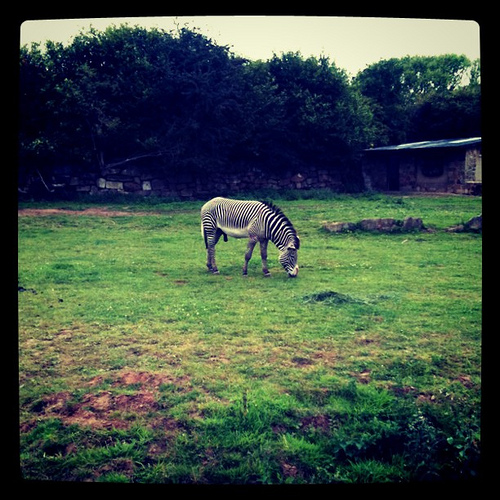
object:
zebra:
[199, 197, 301, 278]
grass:
[17, 190, 483, 486]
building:
[361, 135, 484, 195]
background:
[18, 14, 484, 198]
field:
[19, 195, 485, 484]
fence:
[17, 160, 366, 200]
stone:
[94, 176, 106, 188]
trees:
[236, 48, 373, 170]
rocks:
[446, 213, 483, 235]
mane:
[259, 197, 301, 249]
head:
[278, 240, 301, 278]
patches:
[226, 324, 325, 376]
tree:
[407, 83, 483, 143]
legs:
[205, 225, 221, 276]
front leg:
[258, 238, 272, 277]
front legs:
[242, 231, 260, 276]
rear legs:
[205, 221, 219, 273]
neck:
[264, 203, 299, 250]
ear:
[287, 245, 297, 250]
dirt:
[18, 370, 196, 459]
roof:
[365, 137, 482, 151]